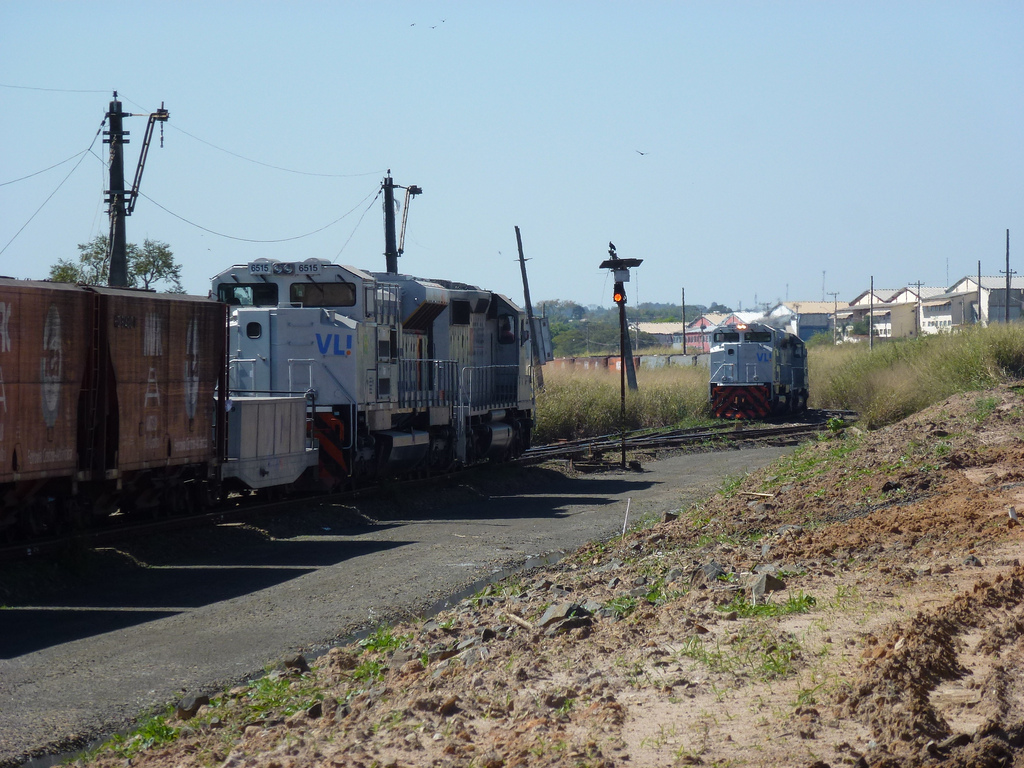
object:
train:
[707, 324, 808, 420]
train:
[0, 258, 553, 534]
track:
[0, 406, 859, 768]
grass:
[536, 365, 695, 431]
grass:
[821, 320, 1023, 425]